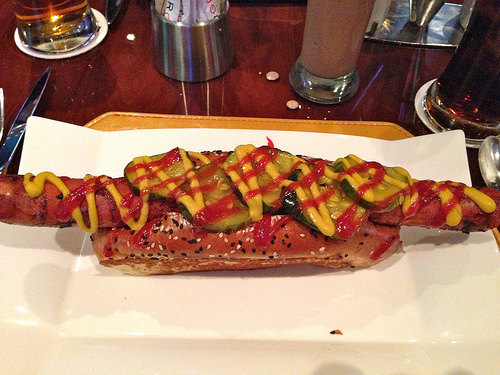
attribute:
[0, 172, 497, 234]
hot dog — long, topped, elaborate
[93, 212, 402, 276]
bun — seeded, seedy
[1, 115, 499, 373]
plate — white, ceramic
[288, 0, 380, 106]
glass — chocolate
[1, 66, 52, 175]
knife — silver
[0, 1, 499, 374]
table — brown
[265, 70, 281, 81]
pill — pink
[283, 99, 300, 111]
pill — pink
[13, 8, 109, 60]
coaster — white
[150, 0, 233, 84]
container — silver, sugar packets